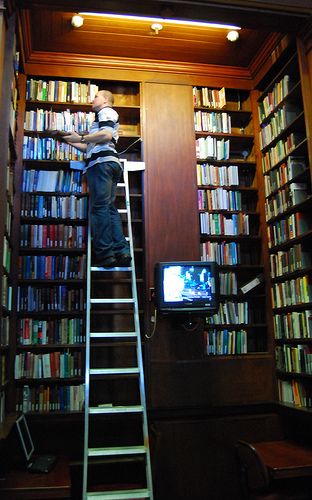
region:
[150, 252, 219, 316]
the tv that is turned on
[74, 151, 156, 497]
the tall ladder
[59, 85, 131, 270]
the man on the ladder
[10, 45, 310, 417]
all the books on the book shelf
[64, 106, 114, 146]
the man's left arm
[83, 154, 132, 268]
the man's legs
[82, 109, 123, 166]
the man's striped shirt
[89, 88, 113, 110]
the man's head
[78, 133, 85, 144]
the watch on the man's left wrist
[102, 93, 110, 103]
the man's left ear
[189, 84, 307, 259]
Quite a few books on a bookshelf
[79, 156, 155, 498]
A very tall ladder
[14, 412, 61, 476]
A desktop computer and keyboard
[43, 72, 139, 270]
A guy putting a book up on a shelf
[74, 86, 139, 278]
A guy wearing a stripped shirt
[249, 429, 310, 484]
A small brown desk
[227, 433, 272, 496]
A brown desk chair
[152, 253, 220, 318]
A t.v. that is on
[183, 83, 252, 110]
The top shelf of a bookshelf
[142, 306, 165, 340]
A white t.v. cable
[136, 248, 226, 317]
the television is on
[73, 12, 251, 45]
the lights on the ceiling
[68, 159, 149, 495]
the ladder is metal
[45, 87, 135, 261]
the man holding a book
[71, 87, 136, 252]
the man wearing jeans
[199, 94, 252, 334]
the books on the shelves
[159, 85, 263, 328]
the shelves are wooden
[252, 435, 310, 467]
the desk below the shelves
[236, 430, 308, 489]
the desk is wooden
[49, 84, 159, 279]
man stand in a ladder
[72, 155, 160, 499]
ladder is high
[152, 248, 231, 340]
a TV monitor color black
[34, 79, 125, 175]
man holds a book in his hand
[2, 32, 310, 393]
shelves of library are full of books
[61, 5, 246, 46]
lights on ceiling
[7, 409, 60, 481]
a computer on a small table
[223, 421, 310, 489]
a small table on side of library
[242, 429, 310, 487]
table is color brown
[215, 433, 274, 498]
a chair is brown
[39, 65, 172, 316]
a man on a ladder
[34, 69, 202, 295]
a man at the top of a ladder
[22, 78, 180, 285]
a man reaching on a bookshelf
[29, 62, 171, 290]
a man holding a book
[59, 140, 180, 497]
a ladder next to book shelf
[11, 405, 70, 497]
a computer on a desk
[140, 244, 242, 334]
a tv on the wall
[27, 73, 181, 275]
a man in a libary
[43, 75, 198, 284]
a man in a library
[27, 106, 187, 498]
a ladder inside a library